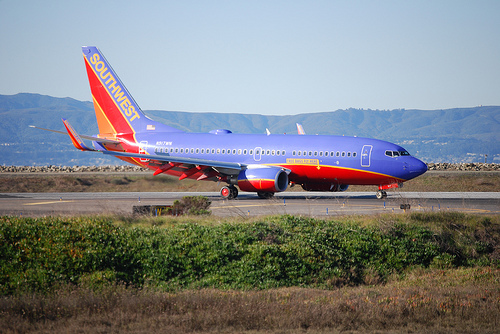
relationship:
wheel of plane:
[215, 184, 242, 204] [26, 42, 426, 200]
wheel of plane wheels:
[217, 184, 238, 199] [372, 187, 391, 203]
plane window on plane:
[150, 147, 160, 154] [57, 46, 440, 211]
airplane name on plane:
[88, 46, 142, 120] [26, 42, 426, 200]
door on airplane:
[248, 141, 268, 165] [22, 40, 433, 204]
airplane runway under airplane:
[7, 189, 499, 216] [41, 40, 449, 213]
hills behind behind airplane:
[5, 89, 499, 166] [22, 40, 433, 204]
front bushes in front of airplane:
[2, 215, 498, 280] [22, 40, 433, 204]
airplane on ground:
[53, 43, 430, 216] [3, 189, 483, 221]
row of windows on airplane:
[152, 144, 254, 153] [22, 40, 433, 204]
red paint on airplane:
[86, 60, 131, 133] [41, 40, 449, 213]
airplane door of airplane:
[358, 139, 379, 174] [22, 40, 433, 204]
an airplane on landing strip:
[27, 46, 429, 200] [6, 181, 484, 216]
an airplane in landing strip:
[27, 46, 429, 200] [4, 184, 484, 220]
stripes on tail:
[74, 42, 169, 165] [80, 44, 153, 136]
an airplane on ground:
[68, 47, 434, 218] [4, 186, 484, 291]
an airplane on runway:
[27, 46, 429, 200] [4, 182, 485, 211]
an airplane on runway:
[27, 46, 429, 200] [1, 180, 485, 234]